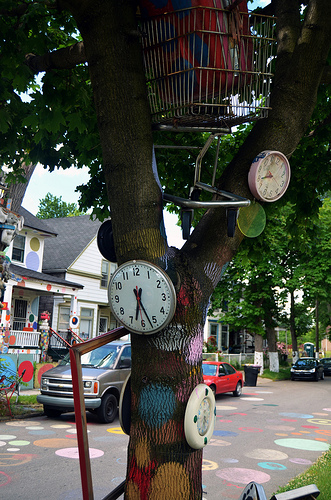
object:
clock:
[102, 259, 173, 329]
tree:
[129, 182, 212, 287]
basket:
[136, 12, 275, 124]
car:
[200, 354, 244, 407]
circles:
[246, 428, 306, 483]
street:
[0, 378, 330, 498]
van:
[38, 339, 136, 431]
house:
[63, 220, 106, 317]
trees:
[19, 29, 73, 143]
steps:
[50, 332, 82, 367]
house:
[14, 225, 53, 341]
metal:
[252, 166, 262, 206]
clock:
[248, 143, 292, 205]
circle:
[138, 375, 176, 432]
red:
[206, 23, 240, 83]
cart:
[148, 123, 252, 239]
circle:
[235, 203, 266, 237]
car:
[288, 355, 323, 390]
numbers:
[155, 282, 165, 324]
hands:
[131, 285, 154, 330]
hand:
[132, 289, 144, 329]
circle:
[184, 330, 205, 362]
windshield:
[202, 363, 224, 380]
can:
[241, 351, 261, 385]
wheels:
[175, 210, 257, 234]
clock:
[176, 375, 228, 445]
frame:
[70, 324, 137, 499]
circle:
[173, 277, 205, 322]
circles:
[26, 234, 45, 272]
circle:
[145, 461, 194, 499]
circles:
[126, 241, 240, 494]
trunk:
[140, 336, 183, 394]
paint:
[10, 415, 94, 454]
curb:
[3, 415, 46, 421]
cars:
[202, 357, 330, 403]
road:
[250, 383, 283, 400]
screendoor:
[99, 312, 115, 348]